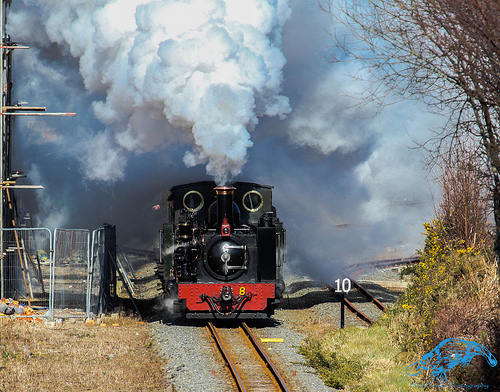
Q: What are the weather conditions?
A: It is cloudy.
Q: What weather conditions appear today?
A: It is cloudy.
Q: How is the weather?
A: It is cloudy.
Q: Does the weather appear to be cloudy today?
A: Yes, it is cloudy.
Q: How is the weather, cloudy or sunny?
A: It is cloudy.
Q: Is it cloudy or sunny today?
A: It is cloudy.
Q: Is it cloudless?
A: No, it is cloudy.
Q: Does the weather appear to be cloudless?
A: No, it is cloudy.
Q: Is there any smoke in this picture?
A: Yes, there is smoke.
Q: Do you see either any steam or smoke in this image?
A: Yes, there is smoke.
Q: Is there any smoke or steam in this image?
A: Yes, there is smoke.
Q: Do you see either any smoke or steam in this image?
A: Yes, there is smoke.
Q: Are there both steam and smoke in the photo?
A: Yes, there are both smoke and steam.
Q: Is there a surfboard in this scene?
A: No, there are no surfboards.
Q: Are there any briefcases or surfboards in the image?
A: No, there are no surfboards or briefcases.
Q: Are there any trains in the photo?
A: Yes, there is a train.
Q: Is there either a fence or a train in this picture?
A: Yes, there is a train.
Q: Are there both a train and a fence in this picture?
A: Yes, there are both a train and a fence.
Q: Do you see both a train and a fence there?
A: Yes, there are both a train and a fence.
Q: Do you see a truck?
A: No, there are no trucks.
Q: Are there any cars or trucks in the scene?
A: No, there are no trucks or cars.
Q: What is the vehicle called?
A: The vehicle is a train.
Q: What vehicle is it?
A: The vehicle is a train.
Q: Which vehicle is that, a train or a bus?
A: This is a train.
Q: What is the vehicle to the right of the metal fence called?
A: The vehicle is a train.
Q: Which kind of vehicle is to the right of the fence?
A: The vehicle is a train.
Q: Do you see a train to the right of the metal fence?
A: Yes, there is a train to the right of the fence.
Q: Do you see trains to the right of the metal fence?
A: Yes, there is a train to the right of the fence.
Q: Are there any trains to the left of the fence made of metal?
A: No, the train is to the right of the fence.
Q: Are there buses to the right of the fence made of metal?
A: No, there is a train to the right of the fence.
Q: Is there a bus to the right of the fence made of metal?
A: No, there is a train to the right of the fence.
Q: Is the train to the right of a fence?
A: Yes, the train is to the right of a fence.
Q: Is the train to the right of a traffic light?
A: No, the train is to the right of a fence.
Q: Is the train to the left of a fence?
A: No, the train is to the right of a fence.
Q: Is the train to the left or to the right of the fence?
A: The train is to the right of the fence.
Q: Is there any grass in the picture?
A: Yes, there is grass.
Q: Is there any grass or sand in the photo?
A: Yes, there is grass.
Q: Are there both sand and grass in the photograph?
A: No, there is grass but no sand.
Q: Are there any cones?
A: No, there are no cones.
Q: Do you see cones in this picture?
A: No, there are no cones.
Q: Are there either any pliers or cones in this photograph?
A: No, there are no cones or pliers.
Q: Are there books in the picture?
A: No, there are no books.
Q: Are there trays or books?
A: No, there are no books or trays.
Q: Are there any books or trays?
A: No, there are no books or trays.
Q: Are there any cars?
A: No, there are no cars.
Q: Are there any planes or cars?
A: No, there are no cars or planes.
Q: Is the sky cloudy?
A: Yes, the sky is cloudy.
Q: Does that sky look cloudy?
A: Yes, the sky is cloudy.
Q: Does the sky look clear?
A: No, the sky is cloudy.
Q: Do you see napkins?
A: No, there are no napkins.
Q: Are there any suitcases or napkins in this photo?
A: No, there are no napkins or suitcases.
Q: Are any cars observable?
A: No, there are no cars.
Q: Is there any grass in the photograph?
A: Yes, there is grass.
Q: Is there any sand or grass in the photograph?
A: Yes, there is grass.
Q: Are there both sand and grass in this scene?
A: No, there is grass but no sand.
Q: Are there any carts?
A: No, there are no carts.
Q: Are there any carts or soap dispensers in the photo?
A: No, there are no carts or soap dispensers.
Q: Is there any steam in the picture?
A: Yes, there is steam.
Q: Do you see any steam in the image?
A: Yes, there is steam.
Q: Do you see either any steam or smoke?
A: Yes, there is steam.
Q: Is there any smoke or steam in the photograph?
A: Yes, there is steam.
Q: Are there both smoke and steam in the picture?
A: Yes, there are both steam and smoke.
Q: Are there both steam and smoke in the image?
A: Yes, there are both steam and smoke.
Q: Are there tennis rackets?
A: No, there are no tennis rackets.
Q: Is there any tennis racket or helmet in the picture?
A: No, there are no rackets or helmets.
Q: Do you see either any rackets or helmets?
A: No, there are no rackets or helmets.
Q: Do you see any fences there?
A: Yes, there is a fence.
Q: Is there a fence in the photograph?
A: Yes, there is a fence.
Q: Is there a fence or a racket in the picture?
A: Yes, there is a fence.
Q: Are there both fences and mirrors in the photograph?
A: No, there is a fence but no mirrors.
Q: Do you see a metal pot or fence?
A: Yes, there is a metal fence.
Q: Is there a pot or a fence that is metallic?
A: Yes, the fence is metallic.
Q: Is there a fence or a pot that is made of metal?
A: Yes, the fence is made of metal.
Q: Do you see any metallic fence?
A: Yes, there is a metal fence.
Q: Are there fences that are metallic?
A: Yes, there is a fence that is metallic.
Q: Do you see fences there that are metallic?
A: Yes, there is a fence that is metallic.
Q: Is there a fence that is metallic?
A: Yes, there is a fence that is metallic.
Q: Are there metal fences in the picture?
A: Yes, there is a fence that is made of metal.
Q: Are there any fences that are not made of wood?
A: Yes, there is a fence that is made of metal.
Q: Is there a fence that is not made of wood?
A: Yes, there is a fence that is made of metal.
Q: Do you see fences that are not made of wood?
A: Yes, there is a fence that is made of metal.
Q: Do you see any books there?
A: No, there are no books.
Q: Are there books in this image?
A: No, there are no books.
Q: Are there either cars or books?
A: No, there are no books or cars.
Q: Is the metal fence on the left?
A: Yes, the fence is on the left of the image.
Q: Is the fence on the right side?
A: No, the fence is on the left of the image.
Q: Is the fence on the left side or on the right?
A: The fence is on the left of the image.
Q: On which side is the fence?
A: The fence is on the left of the image.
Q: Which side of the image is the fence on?
A: The fence is on the left of the image.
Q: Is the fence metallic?
A: Yes, the fence is metallic.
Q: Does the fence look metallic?
A: Yes, the fence is metallic.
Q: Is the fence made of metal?
A: Yes, the fence is made of metal.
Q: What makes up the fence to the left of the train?
A: The fence is made of metal.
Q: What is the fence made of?
A: The fence is made of metal.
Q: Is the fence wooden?
A: No, the fence is metallic.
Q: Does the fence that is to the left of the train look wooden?
A: No, the fence is metallic.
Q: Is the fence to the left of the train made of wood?
A: No, the fence is made of metal.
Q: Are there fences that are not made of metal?
A: No, there is a fence but it is made of metal.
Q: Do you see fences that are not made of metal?
A: No, there is a fence but it is made of metal.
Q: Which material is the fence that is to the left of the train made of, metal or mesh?
A: The fence is made of metal.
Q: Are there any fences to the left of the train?
A: Yes, there is a fence to the left of the train.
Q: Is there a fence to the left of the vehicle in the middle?
A: Yes, there is a fence to the left of the train.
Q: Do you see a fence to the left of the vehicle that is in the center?
A: Yes, there is a fence to the left of the train.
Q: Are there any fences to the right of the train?
A: No, the fence is to the left of the train.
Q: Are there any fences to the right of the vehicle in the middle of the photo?
A: No, the fence is to the left of the train.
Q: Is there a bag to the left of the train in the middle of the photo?
A: No, there is a fence to the left of the train.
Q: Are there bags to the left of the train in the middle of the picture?
A: No, there is a fence to the left of the train.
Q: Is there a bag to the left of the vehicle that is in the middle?
A: No, there is a fence to the left of the train.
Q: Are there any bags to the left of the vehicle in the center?
A: No, there is a fence to the left of the train.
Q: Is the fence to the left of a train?
A: Yes, the fence is to the left of a train.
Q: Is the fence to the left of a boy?
A: No, the fence is to the left of a train.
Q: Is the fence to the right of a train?
A: No, the fence is to the left of a train.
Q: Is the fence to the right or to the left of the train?
A: The fence is to the left of the train.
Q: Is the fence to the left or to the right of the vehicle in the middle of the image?
A: The fence is to the left of the train.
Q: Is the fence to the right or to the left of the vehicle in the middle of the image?
A: The fence is to the left of the train.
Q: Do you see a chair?
A: No, there are no chairs.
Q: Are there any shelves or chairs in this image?
A: No, there are no chairs or shelves.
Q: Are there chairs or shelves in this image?
A: No, there are no chairs or shelves.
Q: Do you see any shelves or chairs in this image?
A: No, there are no chairs or shelves.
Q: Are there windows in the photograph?
A: Yes, there is a window.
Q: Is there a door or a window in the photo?
A: Yes, there is a window.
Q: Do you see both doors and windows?
A: No, there is a window but no doors.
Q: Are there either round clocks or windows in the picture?
A: Yes, there is a round window.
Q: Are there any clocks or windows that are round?
A: Yes, the window is round.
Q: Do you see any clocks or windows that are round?
A: Yes, the window is round.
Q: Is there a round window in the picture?
A: Yes, there is a round window.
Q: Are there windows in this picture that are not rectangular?
A: Yes, there is a round window.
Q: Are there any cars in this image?
A: No, there are no cars.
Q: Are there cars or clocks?
A: No, there are no cars or clocks.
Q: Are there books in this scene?
A: No, there are no books.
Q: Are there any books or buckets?
A: No, there are no books or buckets.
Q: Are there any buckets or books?
A: No, there are no books or buckets.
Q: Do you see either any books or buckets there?
A: No, there are no books or buckets.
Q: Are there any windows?
A: Yes, there is a window.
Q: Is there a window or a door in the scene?
A: Yes, there is a window.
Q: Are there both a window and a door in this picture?
A: No, there is a window but no doors.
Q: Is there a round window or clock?
A: Yes, there is a round window.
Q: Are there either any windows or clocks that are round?
A: Yes, the window is round.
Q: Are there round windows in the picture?
A: Yes, there is a round window.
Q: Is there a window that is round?
A: Yes, there is a window that is round.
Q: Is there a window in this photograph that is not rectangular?
A: Yes, there is a round window.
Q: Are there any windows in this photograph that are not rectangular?
A: Yes, there is a round window.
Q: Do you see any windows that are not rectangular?
A: Yes, there is a round window.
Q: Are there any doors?
A: No, there are no doors.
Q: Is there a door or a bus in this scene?
A: No, there are no doors or buses.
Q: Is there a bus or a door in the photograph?
A: No, there are no doors or buses.